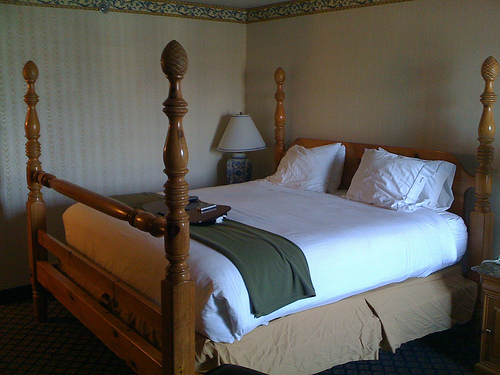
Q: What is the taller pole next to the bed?
A: Part of the frames.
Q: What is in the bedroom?
A: Bed.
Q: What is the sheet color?
A: White.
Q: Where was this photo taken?
A: In a bedroom.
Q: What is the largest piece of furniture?
A: The bed.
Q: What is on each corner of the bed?
A: A bed post.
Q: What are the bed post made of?
A: Wood.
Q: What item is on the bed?
A: A tray.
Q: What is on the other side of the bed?
A: A lamp.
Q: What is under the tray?
A: A blanket.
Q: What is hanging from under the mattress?
A: A bed skirt.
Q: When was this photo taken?
A: In the daytime.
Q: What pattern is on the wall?
A: Stripes.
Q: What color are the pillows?
A: White.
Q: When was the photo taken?
A: Daytime.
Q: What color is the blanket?
A: Green.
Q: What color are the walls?
A: Cream.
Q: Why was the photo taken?
A: To show a room.